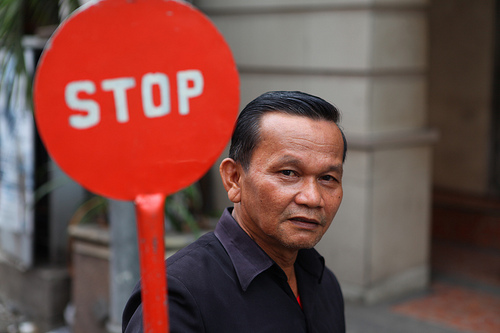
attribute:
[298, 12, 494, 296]
wall — white, gray, brick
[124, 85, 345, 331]
man — Asian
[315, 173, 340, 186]
eye — Asian, man's, staring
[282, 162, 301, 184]
eye — Asian, man's, staring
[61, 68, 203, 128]
word — stop